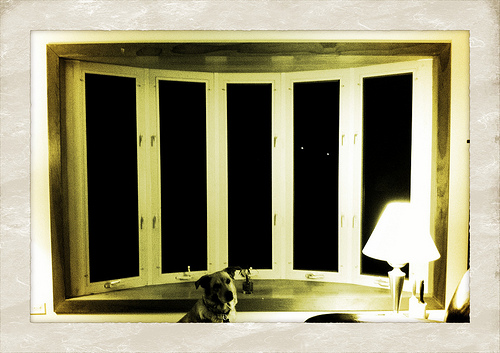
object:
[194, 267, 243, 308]
head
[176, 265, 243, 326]
dog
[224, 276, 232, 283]
eye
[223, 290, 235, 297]
nose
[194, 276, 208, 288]
ear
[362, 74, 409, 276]
shade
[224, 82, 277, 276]
window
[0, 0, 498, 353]
room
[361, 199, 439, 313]
lamp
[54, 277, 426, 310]
ledge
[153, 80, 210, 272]
window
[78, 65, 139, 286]
windows